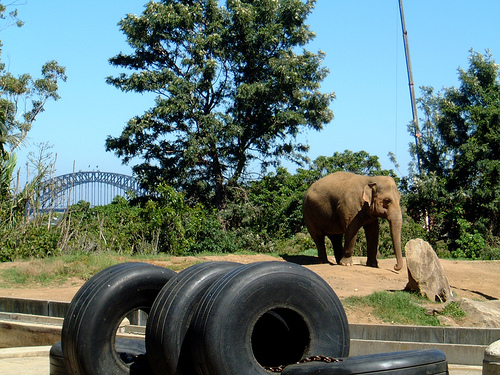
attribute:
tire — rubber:
[283, 346, 448, 371]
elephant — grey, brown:
[301, 173, 402, 270]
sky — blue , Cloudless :
[3, 3, 496, 205]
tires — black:
[51, 260, 448, 373]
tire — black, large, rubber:
[192, 261, 348, 371]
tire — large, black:
[282, 351, 452, 372]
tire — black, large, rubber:
[142, 260, 241, 372]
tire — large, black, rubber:
[59, 261, 179, 372]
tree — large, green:
[398, 46, 498, 258]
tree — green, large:
[0, 9, 68, 243]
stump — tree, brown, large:
[401, 233, 455, 310]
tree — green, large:
[101, 2, 335, 214]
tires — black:
[60, 257, 183, 372]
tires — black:
[142, 248, 255, 368]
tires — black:
[193, 252, 357, 373]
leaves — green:
[103, 0, 336, 209]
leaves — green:
[410, 49, 498, 239]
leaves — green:
[452, 216, 489, 260]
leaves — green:
[350, 149, 381, 172]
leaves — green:
[248, 163, 321, 238]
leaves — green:
[119, 10, 165, 50]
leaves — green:
[104, 46, 166, 68]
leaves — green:
[104, 68, 174, 91]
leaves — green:
[294, 46, 328, 87]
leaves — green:
[301, 89, 335, 130]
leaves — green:
[280, 0, 319, 49]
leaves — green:
[458, 46, 498, 105]